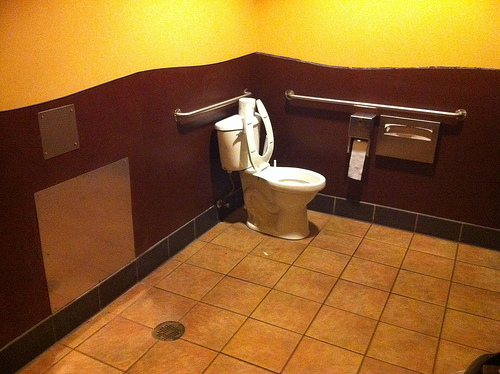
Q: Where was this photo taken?
A: Bathroom.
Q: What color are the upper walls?
A: Yellow.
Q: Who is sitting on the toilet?
A: No one.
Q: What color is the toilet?
A: White.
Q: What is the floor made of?
A: Tiles.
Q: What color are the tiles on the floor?
A: Orange.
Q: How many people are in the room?
A: Zero.